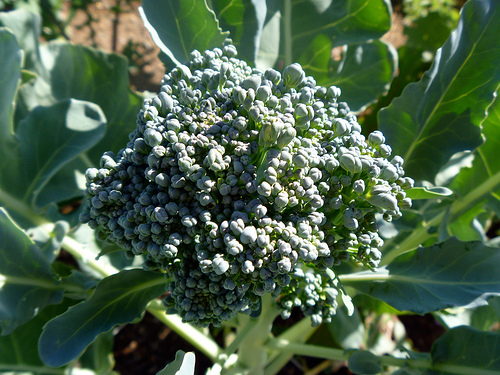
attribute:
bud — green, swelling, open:
[262, 123, 282, 150]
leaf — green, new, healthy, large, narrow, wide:
[373, 7, 498, 179]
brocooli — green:
[53, 22, 478, 339]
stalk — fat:
[230, 293, 279, 374]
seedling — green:
[332, 111, 346, 126]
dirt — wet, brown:
[112, 329, 169, 373]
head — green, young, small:
[75, 44, 414, 322]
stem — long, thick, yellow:
[337, 266, 382, 286]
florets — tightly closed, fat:
[148, 131, 201, 179]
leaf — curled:
[331, 342, 387, 373]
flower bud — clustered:
[344, 172, 409, 228]